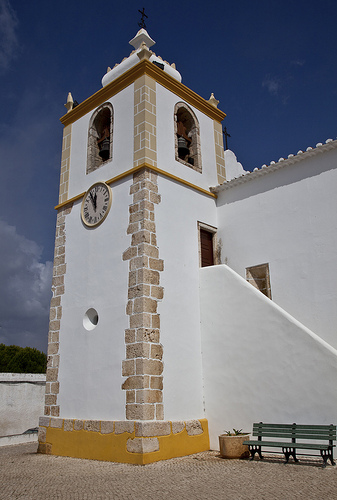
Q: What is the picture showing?
A: It is showing a church.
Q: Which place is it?
A: It is a church.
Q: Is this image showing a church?
A: Yes, it is showing a church.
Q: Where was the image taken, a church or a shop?
A: It was taken at a church.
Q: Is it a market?
A: No, it is a church.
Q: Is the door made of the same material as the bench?
A: Yes, both the door and the bench are made of wood.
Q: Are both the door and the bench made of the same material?
A: Yes, both the door and the bench are made of wood.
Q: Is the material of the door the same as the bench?
A: Yes, both the door and the bench are made of wood.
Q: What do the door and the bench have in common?
A: The material, both the door and the bench are wooden.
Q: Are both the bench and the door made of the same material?
A: Yes, both the bench and the door are made of wood.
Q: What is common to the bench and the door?
A: The material, both the bench and the door are wooden.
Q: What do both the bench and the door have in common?
A: The material, both the bench and the door are wooden.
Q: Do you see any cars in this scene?
A: No, there are no cars.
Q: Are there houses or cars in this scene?
A: No, there are no cars or houses.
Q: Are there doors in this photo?
A: Yes, there is a door.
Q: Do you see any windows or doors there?
A: Yes, there is a door.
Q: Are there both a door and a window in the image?
A: Yes, there are both a door and a window.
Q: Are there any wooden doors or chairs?
A: Yes, there is a wood door.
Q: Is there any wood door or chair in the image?
A: Yes, there is a wood door.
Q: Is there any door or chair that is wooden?
A: Yes, the door is wooden.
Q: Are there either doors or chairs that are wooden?
A: Yes, the door is wooden.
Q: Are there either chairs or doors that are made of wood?
A: Yes, the door is made of wood.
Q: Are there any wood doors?
A: Yes, there is a wood door.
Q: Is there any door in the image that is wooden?
A: Yes, there is a door that is wooden.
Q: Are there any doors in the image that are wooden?
A: Yes, there is a door that is wooden.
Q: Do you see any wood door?
A: Yes, there is a door that is made of wood.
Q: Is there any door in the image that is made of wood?
A: Yes, there is a door that is made of wood.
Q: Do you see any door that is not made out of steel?
A: Yes, there is a door that is made of wood.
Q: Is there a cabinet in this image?
A: No, there are no cabinets.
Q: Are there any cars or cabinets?
A: No, there are no cabinets or cars.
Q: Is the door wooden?
A: Yes, the door is wooden.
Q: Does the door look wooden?
A: Yes, the door is wooden.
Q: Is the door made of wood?
A: Yes, the door is made of wood.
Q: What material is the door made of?
A: The door is made of wood.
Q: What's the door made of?
A: The door is made of wood.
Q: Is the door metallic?
A: No, the door is wooden.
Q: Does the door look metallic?
A: No, the door is wooden.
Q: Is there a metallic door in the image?
A: No, there is a door but it is wooden.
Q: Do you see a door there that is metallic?
A: No, there is a door but it is wooden.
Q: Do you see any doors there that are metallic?
A: No, there is a door but it is wooden.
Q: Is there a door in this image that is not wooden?
A: No, there is a door but it is wooden.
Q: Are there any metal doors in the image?
A: No, there is a door but it is made of wood.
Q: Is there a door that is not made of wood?
A: No, there is a door but it is made of wood.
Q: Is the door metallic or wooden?
A: The door is wooden.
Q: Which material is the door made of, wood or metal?
A: The door is made of wood.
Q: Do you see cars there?
A: No, there are no cars.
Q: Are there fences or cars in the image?
A: No, there are no cars or fences.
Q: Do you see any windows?
A: Yes, there is a window.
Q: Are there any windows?
A: Yes, there is a window.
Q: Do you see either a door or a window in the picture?
A: Yes, there is a window.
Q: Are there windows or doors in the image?
A: Yes, there is a window.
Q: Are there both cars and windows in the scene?
A: No, there is a window but no cars.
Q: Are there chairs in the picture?
A: No, there are no chairs.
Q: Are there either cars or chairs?
A: No, there are no chairs or cars.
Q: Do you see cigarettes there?
A: No, there are no cigarettes.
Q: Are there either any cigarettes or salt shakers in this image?
A: No, there are no cigarettes or salt shakers.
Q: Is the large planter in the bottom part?
A: Yes, the planter is in the bottom of the image.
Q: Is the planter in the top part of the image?
A: No, the planter is in the bottom of the image.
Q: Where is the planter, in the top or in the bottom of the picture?
A: The planter is in the bottom of the image.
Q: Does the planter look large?
A: Yes, the planter is large.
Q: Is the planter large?
A: Yes, the planter is large.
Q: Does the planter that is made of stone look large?
A: Yes, the planter is large.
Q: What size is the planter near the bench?
A: The planter is large.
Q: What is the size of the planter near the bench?
A: The planter is large.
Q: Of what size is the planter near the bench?
A: The planter is large.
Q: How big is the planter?
A: The planter is large.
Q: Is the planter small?
A: No, the planter is large.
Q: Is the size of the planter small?
A: No, the planter is large.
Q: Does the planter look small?
A: No, the planter is large.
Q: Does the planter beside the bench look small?
A: No, the planter is large.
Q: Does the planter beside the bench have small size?
A: No, the planter is large.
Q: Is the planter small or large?
A: The planter is large.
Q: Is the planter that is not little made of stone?
A: Yes, the planter is made of stone.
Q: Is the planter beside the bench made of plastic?
A: No, the planter is made of stone.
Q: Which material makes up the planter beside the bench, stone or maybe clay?
A: The planter is made of stone.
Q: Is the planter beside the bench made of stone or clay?
A: The planter is made of stone.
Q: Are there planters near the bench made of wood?
A: Yes, there is a planter near the bench.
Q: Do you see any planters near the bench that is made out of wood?
A: Yes, there is a planter near the bench.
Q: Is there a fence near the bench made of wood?
A: No, there is a planter near the bench.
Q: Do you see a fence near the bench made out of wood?
A: No, there is a planter near the bench.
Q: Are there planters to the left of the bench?
A: Yes, there is a planter to the left of the bench.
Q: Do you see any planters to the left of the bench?
A: Yes, there is a planter to the left of the bench.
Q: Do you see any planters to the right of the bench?
A: No, the planter is to the left of the bench.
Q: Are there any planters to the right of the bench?
A: No, the planter is to the left of the bench.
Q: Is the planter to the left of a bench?
A: Yes, the planter is to the left of a bench.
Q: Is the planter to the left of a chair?
A: No, the planter is to the left of a bench.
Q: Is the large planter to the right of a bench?
A: No, the planter is to the left of a bench.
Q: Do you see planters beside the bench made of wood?
A: Yes, there is a planter beside the bench.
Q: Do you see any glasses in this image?
A: No, there are no glasses.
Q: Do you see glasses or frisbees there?
A: No, there are no glasses or frisbees.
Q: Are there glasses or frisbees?
A: No, there are no glasses or frisbees.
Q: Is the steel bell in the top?
A: Yes, the bell is in the top of the image.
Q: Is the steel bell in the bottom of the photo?
A: No, the bell is in the top of the image.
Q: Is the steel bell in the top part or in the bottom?
A: The bell is in the top of the image.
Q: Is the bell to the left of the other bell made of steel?
A: Yes, the bell is made of steel.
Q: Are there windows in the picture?
A: Yes, there is a window.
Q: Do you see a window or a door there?
A: Yes, there is a window.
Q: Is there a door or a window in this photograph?
A: Yes, there is a window.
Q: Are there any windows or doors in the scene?
A: Yes, there is a window.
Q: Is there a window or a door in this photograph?
A: Yes, there is a window.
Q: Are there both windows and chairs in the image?
A: No, there is a window but no chairs.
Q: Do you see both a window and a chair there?
A: No, there is a window but no chairs.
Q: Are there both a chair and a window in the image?
A: No, there is a window but no chairs.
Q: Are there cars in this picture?
A: No, there are no cars.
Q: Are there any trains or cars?
A: No, there are no cars or trains.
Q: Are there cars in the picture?
A: No, there are no cars.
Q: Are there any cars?
A: No, there are no cars.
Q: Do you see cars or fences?
A: No, there are no cars or fences.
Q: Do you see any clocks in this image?
A: Yes, there is a clock.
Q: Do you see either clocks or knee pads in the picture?
A: Yes, there is a clock.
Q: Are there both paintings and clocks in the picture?
A: No, there is a clock but no paintings.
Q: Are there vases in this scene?
A: No, there are no vases.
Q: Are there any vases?
A: No, there are no vases.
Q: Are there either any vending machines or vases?
A: No, there are no vases or vending machines.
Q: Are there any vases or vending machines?
A: No, there are no vases or vending machines.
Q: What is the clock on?
A: The clock is on the tower.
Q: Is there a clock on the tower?
A: Yes, there is a clock on the tower.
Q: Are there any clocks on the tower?
A: Yes, there is a clock on the tower.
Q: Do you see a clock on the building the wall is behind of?
A: Yes, there is a clock on the tower.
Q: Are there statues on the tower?
A: No, there is a clock on the tower.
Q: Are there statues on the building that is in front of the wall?
A: No, there is a clock on the tower.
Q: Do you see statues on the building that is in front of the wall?
A: No, there is a clock on the tower.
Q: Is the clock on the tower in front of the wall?
A: Yes, the clock is on the tower.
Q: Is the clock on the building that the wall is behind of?
A: Yes, the clock is on the tower.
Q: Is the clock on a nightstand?
A: No, the clock is on the tower.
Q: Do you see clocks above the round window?
A: Yes, there is a clock above the window.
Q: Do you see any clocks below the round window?
A: No, the clock is above the window.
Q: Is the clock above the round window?
A: Yes, the clock is above the window.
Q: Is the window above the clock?
A: No, the clock is above the window.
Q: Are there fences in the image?
A: No, there are no fences.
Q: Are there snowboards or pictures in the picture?
A: No, there are no pictures or snowboards.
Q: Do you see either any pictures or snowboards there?
A: No, there are no pictures or snowboards.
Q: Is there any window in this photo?
A: Yes, there is a window.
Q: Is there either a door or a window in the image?
A: Yes, there is a window.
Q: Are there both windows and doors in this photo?
A: Yes, there are both a window and a door.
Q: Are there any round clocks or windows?
A: Yes, there is a round window.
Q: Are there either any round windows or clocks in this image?
A: Yes, there is a round window.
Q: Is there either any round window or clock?
A: Yes, there is a round window.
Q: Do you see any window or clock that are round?
A: Yes, the window is round.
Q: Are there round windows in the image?
A: Yes, there is a round window.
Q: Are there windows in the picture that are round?
A: Yes, there is a window that is round.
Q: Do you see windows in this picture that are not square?
A: Yes, there is a round window.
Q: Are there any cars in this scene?
A: No, there are no cars.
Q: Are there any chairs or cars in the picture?
A: No, there are no cars or chairs.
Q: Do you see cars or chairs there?
A: No, there are no cars or chairs.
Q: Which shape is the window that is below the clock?
A: The window is round.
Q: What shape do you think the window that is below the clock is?
A: The window is round.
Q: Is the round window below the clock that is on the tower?
A: Yes, the window is below the clock.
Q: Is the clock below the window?
A: No, the window is below the clock.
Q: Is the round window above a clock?
A: No, the window is below a clock.